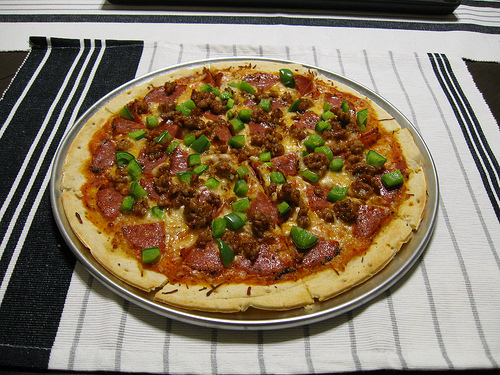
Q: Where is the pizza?
A: In the pan.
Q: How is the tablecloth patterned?
A: Striped.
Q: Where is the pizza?
A: On the table top.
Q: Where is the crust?
A: Around the pizza.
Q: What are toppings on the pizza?
A: Pepperoni and sausage.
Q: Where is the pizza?
A: Plate.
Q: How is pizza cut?
A: Sliced.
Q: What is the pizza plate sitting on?
A: Table.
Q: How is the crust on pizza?
A: Thin.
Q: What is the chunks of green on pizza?
A: Bell peppers.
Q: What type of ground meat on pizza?
A: Beef.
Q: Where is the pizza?
A: On table.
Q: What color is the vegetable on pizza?
A: Green.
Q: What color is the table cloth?
A: Black and white.